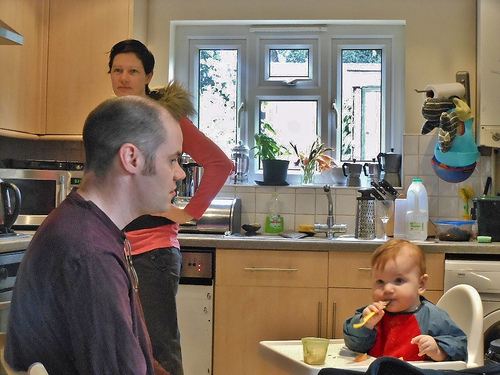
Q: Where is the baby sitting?
A: A highchair.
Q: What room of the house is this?
A: Kitchen.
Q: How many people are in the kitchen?
A: 3.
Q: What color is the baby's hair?
A: Red.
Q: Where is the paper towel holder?
A: Hanging from the cabinet beside the window.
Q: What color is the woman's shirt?
A: Red.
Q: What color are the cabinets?
A: Light brown.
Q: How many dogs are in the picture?
A: None.